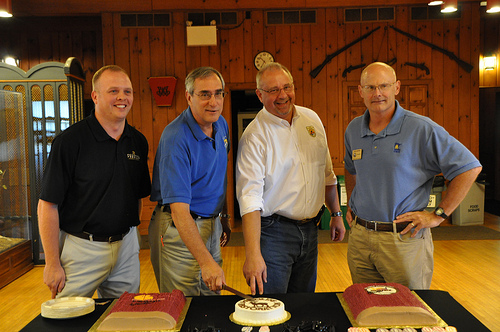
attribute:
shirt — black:
[53, 110, 161, 256]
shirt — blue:
[156, 110, 237, 210]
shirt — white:
[240, 95, 343, 243]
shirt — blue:
[317, 95, 469, 248]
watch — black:
[429, 202, 448, 220]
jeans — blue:
[243, 212, 331, 283]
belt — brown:
[333, 202, 412, 242]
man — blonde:
[61, 47, 160, 171]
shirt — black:
[53, 122, 172, 244]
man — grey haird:
[167, 70, 258, 170]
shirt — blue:
[160, 111, 243, 211]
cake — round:
[227, 293, 287, 323]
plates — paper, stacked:
[36, 293, 96, 320]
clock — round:
[252, 47, 276, 69]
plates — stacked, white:
[36, 294, 96, 322]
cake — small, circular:
[229, 293, 292, 326]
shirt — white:
[232, 102, 339, 222]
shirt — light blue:
[340, 100, 480, 224]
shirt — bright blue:
[147, 107, 233, 221]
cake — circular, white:
[232, 295, 289, 325]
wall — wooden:
[81, 0, 479, 230]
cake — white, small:
[228, 295, 303, 328]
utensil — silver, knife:
[220, 278, 249, 306]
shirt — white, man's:
[236, 108, 335, 248]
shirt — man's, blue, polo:
[154, 109, 224, 223]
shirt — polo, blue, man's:
[343, 112, 475, 231]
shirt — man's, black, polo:
[33, 114, 154, 254]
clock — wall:
[254, 44, 278, 70]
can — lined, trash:
[452, 182, 483, 228]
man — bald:
[337, 62, 470, 296]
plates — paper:
[39, 293, 95, 317]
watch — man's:
[433, 205, 453, 225]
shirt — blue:
[156, 106, 234, 219]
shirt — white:
[233, 106, 334, 224]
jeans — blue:
[256, 209, 319, 292]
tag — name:
[349, 149, 363, 162]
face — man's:
[185, 64, 225, 122]